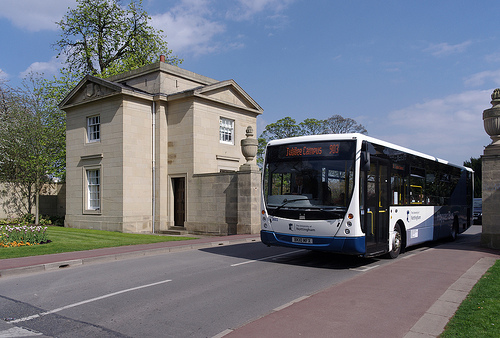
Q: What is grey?
A: Ground.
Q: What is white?
A: Lines on the road.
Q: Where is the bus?
A: On the road.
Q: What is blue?
A: Sky.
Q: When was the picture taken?
A: Daytime.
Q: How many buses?
A: One.